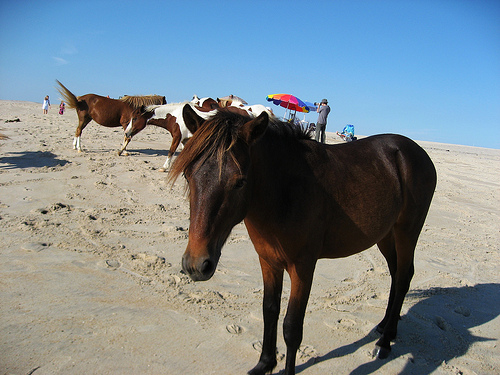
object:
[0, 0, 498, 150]
sky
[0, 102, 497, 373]
ground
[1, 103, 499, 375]
sand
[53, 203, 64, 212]
track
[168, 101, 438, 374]
horse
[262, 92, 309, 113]
umbrella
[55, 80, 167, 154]
horse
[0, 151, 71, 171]
shadow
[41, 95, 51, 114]
person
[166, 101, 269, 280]
head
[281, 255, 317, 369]
leg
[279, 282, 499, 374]
shadow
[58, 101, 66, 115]
person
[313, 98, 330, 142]
man